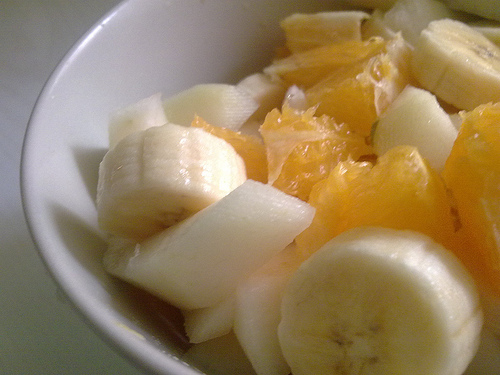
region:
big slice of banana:
[281, 223, 484, 374]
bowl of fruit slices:
[104, 3, 499, 371]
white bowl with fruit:
[16, 0, 496, 370]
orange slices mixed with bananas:
[100, 7, 498, 370]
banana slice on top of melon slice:
[92, 120, 317, 312]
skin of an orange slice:
[261, 113, 330, 183]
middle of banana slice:
[317, 307, 394, 372]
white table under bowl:
[0, 1, 120, 372]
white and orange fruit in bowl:
[101, 4, 496, 366]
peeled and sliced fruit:
[100, 6, 496, 373]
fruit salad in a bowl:
[51, 4, 486, 355]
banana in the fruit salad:
[90, 112, 249, 227]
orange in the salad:
[279, 105, 466, 265]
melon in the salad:
[99, 179, 321, 309]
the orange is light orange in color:
[251, 97, 432, 253]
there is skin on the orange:
[240, 92, 311, 196]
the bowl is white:
[10, 11, 477, 370]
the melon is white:
[135, 177, 322, 295]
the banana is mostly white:
[97, 128, 214, 228]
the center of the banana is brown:
[321, 290, 399, 372]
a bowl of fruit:
[19, 1, 499, 373]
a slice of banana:
[278, 224, 483, 374]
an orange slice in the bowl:
[311, 147, 499, 227]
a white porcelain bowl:
[21, 0, 139, 348]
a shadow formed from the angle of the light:
[42, 142, 102, 274]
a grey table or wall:
[1, 1, 21, 373]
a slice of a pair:
[154, 179, 314, 316]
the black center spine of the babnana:
[324, 311, 390, 373]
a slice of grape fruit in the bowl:
[262, 105, 349, 186]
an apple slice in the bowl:
[377, 85, 457, 164]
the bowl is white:
[14, 26, 253, 360]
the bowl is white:
[79, 123, 236, 366]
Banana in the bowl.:
[105, 79, 247, 218]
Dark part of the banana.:
[302, 314, 359, 374]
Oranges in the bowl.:
[185, 82, 445, 259]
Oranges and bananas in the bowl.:
[21, 7, 496, 301]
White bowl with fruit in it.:
[17, 12, 420, 369]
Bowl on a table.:
[18, 14, 488, 346]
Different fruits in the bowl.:
[100, 58, 497, 349]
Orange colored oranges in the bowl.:
[228, 86, 405, 248]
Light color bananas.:
[92, 115, 325, 245]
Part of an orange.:
[225, 95, 338, 197]